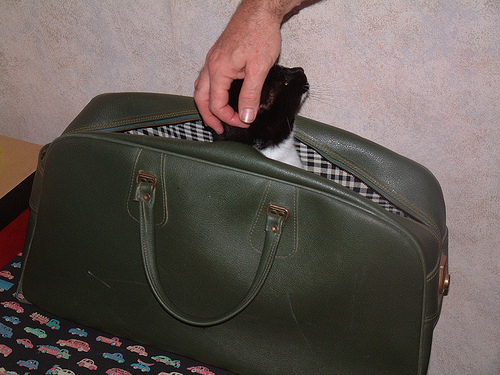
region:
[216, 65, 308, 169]
black and white kitten in a green bag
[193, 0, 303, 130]
Hand is petting the kitten.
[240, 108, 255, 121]
Fingernail on the thumb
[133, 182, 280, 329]
Handle on the green bag.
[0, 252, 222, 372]
little cars printed on the table cloth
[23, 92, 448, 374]
dark green bag with a kitten in it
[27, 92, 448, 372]
dark green bag sitting on a table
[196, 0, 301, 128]
hair arm touching the kitten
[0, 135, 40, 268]
black and white shoe box behind the bag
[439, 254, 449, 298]
buckle on the side of the bag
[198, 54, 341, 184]
cat head being stroked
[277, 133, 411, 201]
zipper on the bag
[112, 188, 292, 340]
handle of the bag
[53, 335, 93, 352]
car on the pattern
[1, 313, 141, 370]
car pattern on the fabric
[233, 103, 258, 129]
nail on the finger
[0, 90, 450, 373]
bag on the table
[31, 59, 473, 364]
cat in a bag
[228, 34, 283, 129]
thumb of the hand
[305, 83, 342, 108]
whiskers on the cat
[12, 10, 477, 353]
a cat in a bag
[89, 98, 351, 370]
the bag is green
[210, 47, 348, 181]
a black and white cat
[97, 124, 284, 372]
a handle on the bag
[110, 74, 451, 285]
the bag is open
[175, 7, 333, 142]
a hand on the cat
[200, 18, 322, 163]
the hand is on the head of the cat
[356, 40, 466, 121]
the wall is light gray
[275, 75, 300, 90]
the cat has eyes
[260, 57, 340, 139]
the cat has whiskers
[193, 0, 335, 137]
a hand with an unknown body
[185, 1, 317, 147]
a hand petting a black and white kitty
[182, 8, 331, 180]
a blak and white kitty being petted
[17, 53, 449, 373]
a cat inside of a small green tote bag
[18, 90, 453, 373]
a plain green tote bag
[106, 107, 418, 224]
black and white checkerboard lining in a purse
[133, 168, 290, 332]
a hunter green purse handle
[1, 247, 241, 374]
a table with colorful cartoon cars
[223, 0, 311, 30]
a man's hairy wrist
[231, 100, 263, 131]
a thumb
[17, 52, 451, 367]
Cat in a green back.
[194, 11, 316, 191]
Person petting a cat in a bag.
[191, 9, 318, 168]
Cat with man's hand on his head.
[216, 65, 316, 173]
Cat is black and white.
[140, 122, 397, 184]
Bag's lining made of black and white plaid fabric.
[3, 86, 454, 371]
The bag is on a mat.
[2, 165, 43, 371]
The mat has black and red borders.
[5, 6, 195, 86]
Wall is covered with marble looking tiles.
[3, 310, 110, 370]
The small car prints on the mat are colorful.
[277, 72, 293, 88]
The cats' eyes are closed.